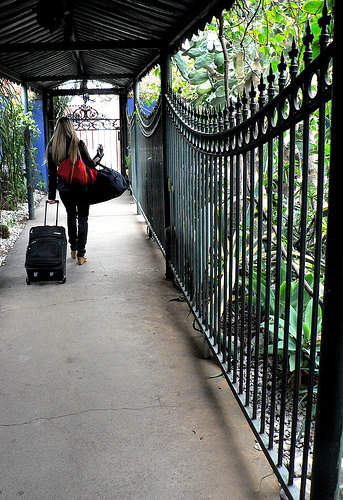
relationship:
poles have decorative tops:
[0, 0, 342, 500] [123, 0, 342, 128]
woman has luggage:
[46, 117, 105, 265] [25, 167, 129, 283]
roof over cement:
[0, 0, 238, 92] [0, 175, 295, 499]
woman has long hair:
[46, 117, 105, 265] [51, 117, 80, 165]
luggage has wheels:
[24, 201, 68, 287] [24, 276, 66, 284]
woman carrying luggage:
[46, 117, 105, 265] [25, 167, 129, 283]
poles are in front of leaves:
[0, 0, 342, 500] [0, 0, 342, 371]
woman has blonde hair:
[46, 117, 105, 265] [51, 117, 80, 165]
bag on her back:
[56, 158, 98, 183] [51, 138, 89, 201]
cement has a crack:
[0, 175, 295, 499] [0, 402, 184, 430]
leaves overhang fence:
[0, 0, 342, 371] [0, 0, 342, 500]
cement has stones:
[0, 175, 295, 499] [0, 183, 45, 265]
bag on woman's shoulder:
[56, 158, 98, 183] [47, 139, 85, 149]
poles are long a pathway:
[0, 0, 342, 500] [0, 175, 295, 499]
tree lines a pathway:
[138, 0, 337, 249] [0, 175, 295, 499]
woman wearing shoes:
[46, 117, 105, 265] [71, 248, 87, 265]